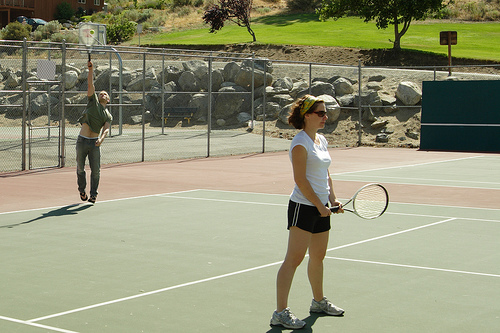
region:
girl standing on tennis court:
[268, 93, 341, 329]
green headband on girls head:
[295, 90, 315, 115]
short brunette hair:
[285, 91, 320, 126]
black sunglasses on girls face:
[310, 101, 325, 116]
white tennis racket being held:
[327, 180, 387, 220]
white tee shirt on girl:
[287, 130, 332, 205]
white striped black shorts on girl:
[280, 200, 330, 230]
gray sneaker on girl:
[265, 310, 306, 330]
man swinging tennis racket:
[72, 60, 108, 202]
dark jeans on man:
[75, 132, 101, 197]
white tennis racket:
[62, 14, 114, 71]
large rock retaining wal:
[143, 46, 271, 154]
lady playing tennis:
[270, 87, 385, 330]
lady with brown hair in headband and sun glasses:
[282, 89, 349, 144]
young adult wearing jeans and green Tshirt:
[73, 46, 123, 219]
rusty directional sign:
[432, 17, 469, 83]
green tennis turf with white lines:
[21, 186, 328, 331]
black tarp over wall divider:
[412, 74, 497, 167]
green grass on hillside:
[260, 8, 462, 50]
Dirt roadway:
[123, 45, 495, 81]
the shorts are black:
[275, 202, 356, 228]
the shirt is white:
[295, 140, 381, 210]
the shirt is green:
[76, 98, 125, 133]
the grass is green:
[282, 22, 366, 41]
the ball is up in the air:
[68, 24, 117, 49]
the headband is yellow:
[287, 89, 352, 126]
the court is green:
[75, 212, 186, 260]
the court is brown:
[200, 161, 282, 185]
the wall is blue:
[425, 84, 498, 152]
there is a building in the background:
[24, 2, 83, 21]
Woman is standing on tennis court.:
[262, 95, 396, 331]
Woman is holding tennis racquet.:
[319, 182, 392, 227]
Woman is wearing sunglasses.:
[308, 106, 330, 123]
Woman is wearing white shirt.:
[284, 129, 338, 216]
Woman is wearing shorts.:
[277, 197, 344, 244]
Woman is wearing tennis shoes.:
[265, 297, 345, 332]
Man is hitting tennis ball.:
[68, 20, 111, 75]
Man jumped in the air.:
[67, 12, 122, 217]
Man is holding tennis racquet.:
[78, 19, 100, 70]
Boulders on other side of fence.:
[3, 51, 418, 148]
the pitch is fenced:
[140, 62, 272, 155]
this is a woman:
[270, 98, 348, 326]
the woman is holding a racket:
[312, 182, 391, 219]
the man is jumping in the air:
[73, 22, 113, 203]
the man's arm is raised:
[76, 21, 101, 81]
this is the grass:
[278, 15, 348, 39]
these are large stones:
[161, 58, 273, 122]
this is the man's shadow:
[36, 198, 93, 219]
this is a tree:
[328, 0, 433, 60]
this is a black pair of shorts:
[285, 205, 307, 225]